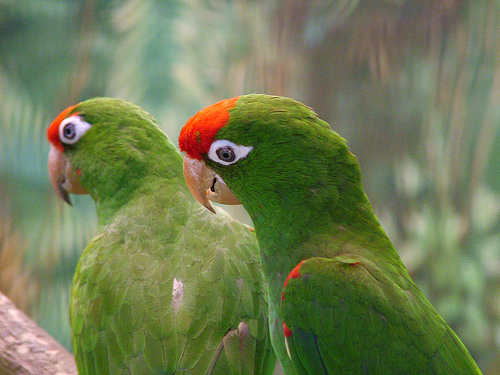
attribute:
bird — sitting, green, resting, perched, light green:
[178, 94, 482, 373]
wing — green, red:
[280, 252, 449, 374]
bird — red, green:
[45, 95, 275, 374]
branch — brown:
[0, 292, 75, 373]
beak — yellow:
[183, 156, 243, 214]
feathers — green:
[179, 93, 482, 374]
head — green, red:
[46, 96, 183, 226]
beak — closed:
[49, 143, 89, 205]